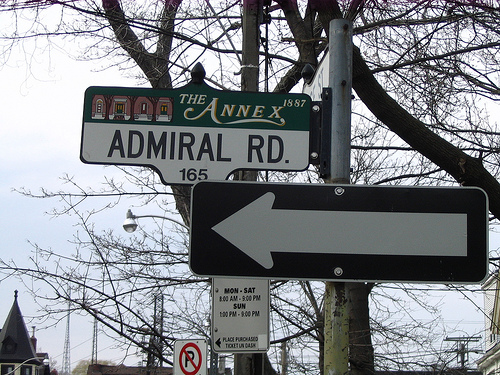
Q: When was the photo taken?
A: During the day.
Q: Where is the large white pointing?
A: To the left.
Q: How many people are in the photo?
A: None.